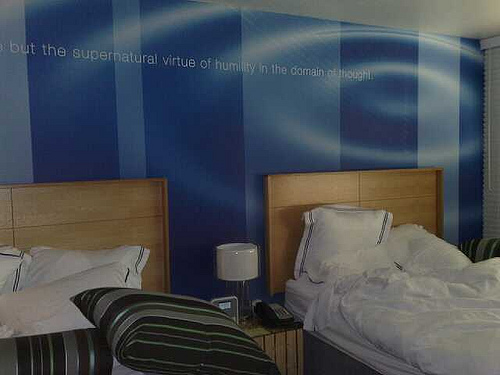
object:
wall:
[0, 3, 485, 308]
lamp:
[215, 240, 261, 330]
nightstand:
[238, 308, 307, 374]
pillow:
[64, 286, 278, 373]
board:
[264, 164, 445, 301]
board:
[0, 176, 170, 293]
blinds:
[479, 35, 499, 240]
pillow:
[385, 219, 460, 273]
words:
[9, 38, 20, 53]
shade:
[215, 242, 258, 281]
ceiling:
[220, 0, 498, 41]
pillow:
[293, 205, 391, 281]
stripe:
[24, 3, 120, 187]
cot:
[275, 264, 499, 374]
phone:
[253, 301, 305, 330]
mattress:
[283, 277, 322, 323]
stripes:
[59, 330, 80, 374]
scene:
[0, 2, 498, 374]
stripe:
[132, 335, 278, 366]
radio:
[209, 295, 240, 324]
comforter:
[309, 268, 499, 374]